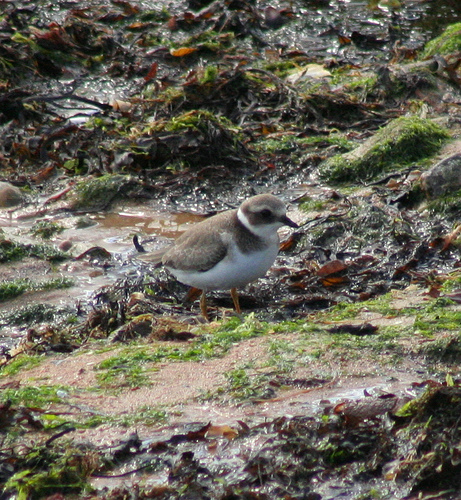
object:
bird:
[131, 192, 299, 321]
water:
[0, 195, 72, 302]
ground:
[306, 0, 459, 497]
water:
[305, 34, 335, 93]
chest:
[213, 233, 281, 288]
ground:
[85, 297, 339, 463]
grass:
[178, 62, 286, 110]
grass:
[322, 110, 455, 182]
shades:
[315, 100, 367, 119]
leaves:
[299, 80, 344, 101]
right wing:
[136, 227, 227, 272]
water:
[103, 204, 195, 252]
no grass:
[151, 366, 203, 398]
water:
[57, 186, 240, 250]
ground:
[350, 106, 411, 156]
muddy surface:
[2, 2, 459, 498]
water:
[106, 208, 173, 240]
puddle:
[82, 186, 190, 262]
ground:
[174, 361, 339, 409]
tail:
[133, 234, 148, 253]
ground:
[159, 346, 329, 406]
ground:
[149, 365, 311, 408]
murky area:
[331, 204, 386, 239]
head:
[238, 193, 298, 232]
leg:
[199, 291, 208, 320]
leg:
[229, 287, 242, 313]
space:
[164, 342, 241, 388]